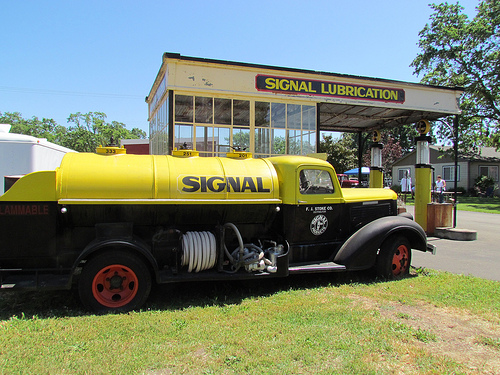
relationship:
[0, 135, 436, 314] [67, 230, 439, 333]
truck has rims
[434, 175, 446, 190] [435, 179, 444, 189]
woman wearing shirt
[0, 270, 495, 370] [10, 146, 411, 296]
grass by truck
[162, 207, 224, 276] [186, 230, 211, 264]
reel hose has hose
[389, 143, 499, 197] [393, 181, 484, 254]
house across road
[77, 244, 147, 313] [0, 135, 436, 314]
wheel on truck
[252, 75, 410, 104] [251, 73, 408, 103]
sign on sign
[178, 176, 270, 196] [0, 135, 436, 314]
logo on truck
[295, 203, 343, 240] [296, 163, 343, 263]
white logo on door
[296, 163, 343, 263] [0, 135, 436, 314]
door on truck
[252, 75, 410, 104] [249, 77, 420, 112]
sign on sign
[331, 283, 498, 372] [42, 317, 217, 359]
patch on grass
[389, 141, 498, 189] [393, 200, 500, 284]
house on other side of road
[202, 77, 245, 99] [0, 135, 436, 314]
wall on truck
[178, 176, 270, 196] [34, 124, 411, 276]
logo on truck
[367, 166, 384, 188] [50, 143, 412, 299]
pylon near truck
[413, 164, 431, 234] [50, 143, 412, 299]
pylon near truck